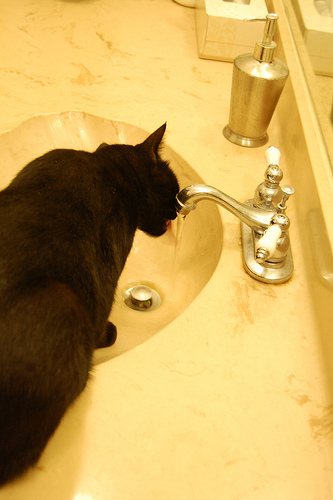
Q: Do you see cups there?
A: No, there are no cups.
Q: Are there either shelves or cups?
A: No, there are no cups or shelves.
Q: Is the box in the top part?
A: Yes, the box is in the top of the image.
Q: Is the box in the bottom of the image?
A: No, the box is in the top of the image.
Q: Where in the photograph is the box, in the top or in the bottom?
A: The box is in the top of the image.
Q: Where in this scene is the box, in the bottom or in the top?
A: The box is in the top of the image.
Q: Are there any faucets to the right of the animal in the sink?
A: Yes, there is a faucet to the right of the cat.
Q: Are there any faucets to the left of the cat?
A: No, the faucet is to the right of the cat.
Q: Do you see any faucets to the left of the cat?
A: No, the faucet is to the right of the cat.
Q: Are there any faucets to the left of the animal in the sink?
A: No, the faucet is to the right of the cat.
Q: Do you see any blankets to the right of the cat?
A: No, there is a faucet to the right of the cat.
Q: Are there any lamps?
A: No, there are no lamps.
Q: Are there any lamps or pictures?
A: No, there are no lamps or pictures.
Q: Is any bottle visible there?
A: Yes, there is a bottle.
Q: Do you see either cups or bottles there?
A: Yes, there is a bottle.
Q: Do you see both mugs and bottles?
A: No, there is a bottle but no mugs.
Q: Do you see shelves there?
A: No, there are no shelves.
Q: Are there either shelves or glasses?
A: No, there are no shelves or glasses.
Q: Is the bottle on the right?
A: Yes, the bottle is on the right of the image.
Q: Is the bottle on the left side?
A: No, the bottle is on the right of the image.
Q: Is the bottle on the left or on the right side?
A: The bottle is on the right of the image.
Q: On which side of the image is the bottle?
A: The bottle is on the right of the image.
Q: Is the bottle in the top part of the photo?
A: Yes, the bottle is in the top of the image.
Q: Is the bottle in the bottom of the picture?
A: No, the bottle is in the top of the image.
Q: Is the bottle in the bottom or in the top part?
A: The bottle is in the top of the image.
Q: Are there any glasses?
A: No, there are no glasses.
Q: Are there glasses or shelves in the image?
A: No, there are no glasses or shelves.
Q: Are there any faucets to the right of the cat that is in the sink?
A: Yes, there is a faucet to the right of the cat.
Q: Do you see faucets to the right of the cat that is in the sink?
A: Yes, there is a faucet to the right of the cat.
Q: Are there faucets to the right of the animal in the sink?
A: Yes, there is a faucet to the right of the cat.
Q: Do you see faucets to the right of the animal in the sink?
A: Yes, there is a faucet to the right of the cat.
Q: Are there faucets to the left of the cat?
A: No, the faucet is to the right of the cat.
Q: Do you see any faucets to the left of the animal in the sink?
A: No, the faucet is to the right of the cat.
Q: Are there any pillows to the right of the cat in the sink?
A: No, there is a faucet to the right of the cat.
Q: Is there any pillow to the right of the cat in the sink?
A: No, there is a faucet to the right of the cat.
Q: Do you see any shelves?
A: No, there are no shelves.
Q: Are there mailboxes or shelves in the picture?
A: No, there are no shelves or mailboxes.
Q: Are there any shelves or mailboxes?
A: No, there are no shelves or mailboxes.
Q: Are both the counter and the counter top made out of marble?
A: Yes, both the counter and the counter top are made of marble.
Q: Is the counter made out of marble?
A: Yes, the counter is made of marble.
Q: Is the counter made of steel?
A: No, the counter is made of marble.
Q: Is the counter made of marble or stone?
A: The counter is made of marble.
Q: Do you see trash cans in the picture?
A: No, there are no trash cans.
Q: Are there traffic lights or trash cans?
A: No, there are no trash cans or traffic lights.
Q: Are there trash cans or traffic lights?
A: No, there are no trash cans or traffic lights.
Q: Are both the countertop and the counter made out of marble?
A: Yes, both the countertop and the counter are made of marble.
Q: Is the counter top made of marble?
A: Yes, the counter top is made of marble.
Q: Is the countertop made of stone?
A: No, the countertop is made of marble.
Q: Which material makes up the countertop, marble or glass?
A: The countertop is made of marble.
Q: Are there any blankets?
A: No, there are no blankets.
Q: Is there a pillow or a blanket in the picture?
A: No, there are no blankets or pillows.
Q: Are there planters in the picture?
A: No, there are no planters.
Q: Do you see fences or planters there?
A: No, there are no planters or fences.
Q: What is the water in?
A: The water is in the sink.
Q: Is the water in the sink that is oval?
A: Yes, the water is in the sink.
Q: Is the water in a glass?
A: No, the water is in the sink.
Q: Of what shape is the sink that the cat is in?
A: The sink is round.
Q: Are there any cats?
A: Yes, there is a cat.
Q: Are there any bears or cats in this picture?
A: Yes, there is a cat.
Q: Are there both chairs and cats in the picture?
A: No, there is a cat but no chairs.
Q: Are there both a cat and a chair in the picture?
A: No, there is a cat but no chairs.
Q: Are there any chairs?
A: No, there are no chairs.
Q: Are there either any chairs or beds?
A: No, there are no chairs or beds.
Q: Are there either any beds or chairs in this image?
A: No, there are no chairs or beds.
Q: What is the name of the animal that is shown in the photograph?
A: The animal is a cat.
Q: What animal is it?
A: The animal is a cat.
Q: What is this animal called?
A: That is a cat.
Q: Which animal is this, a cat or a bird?
A: That is a cat.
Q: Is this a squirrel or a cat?
A: This is a cat.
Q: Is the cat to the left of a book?
A: No, the cat is to the left of the tap.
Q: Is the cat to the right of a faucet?
A: No, the cat is to the left of a faucet.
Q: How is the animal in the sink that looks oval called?
A: The animal is a cat.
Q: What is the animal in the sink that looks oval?
A: The animal is a cat.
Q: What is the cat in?
A: The cat is in the sink.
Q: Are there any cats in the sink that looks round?
A: Yes, there is a cat in the sink.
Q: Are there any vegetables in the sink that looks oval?
A: No, there is a cat in the sink.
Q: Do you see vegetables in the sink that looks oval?
A: No, there is a cat in the sink.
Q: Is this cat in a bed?
A: No, the cat is in the sink.